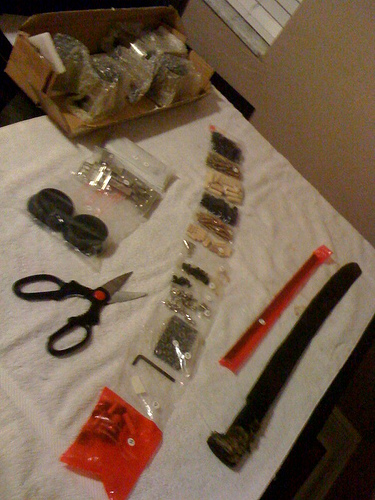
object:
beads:
[160, 336, 166, 345]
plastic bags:
[108, 351, 183, 428]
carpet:
[297, 406, 362, 498]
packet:
[60, 387, 162, 499]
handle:
[207, 404, 258, 468]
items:
[11, 270, 146, 359]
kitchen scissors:
[13, 269, 149, 356]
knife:
[206, 262, 362, 467]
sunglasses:
[28, 186, 109, 257]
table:
[0, 85, 375, 498]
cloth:
[0, 83, 375, 498]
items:
[48, 29, 97, 106]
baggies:
[82, 56, 119, 121]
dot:
[93, 285, 105, 302]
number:
[127, 435, 135, 447]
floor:
[181, 0, 375, 247]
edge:
[105, 385, 160, 435]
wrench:
[130, 354, 175, 385]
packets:
[218, 245, 333, 370]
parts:
[170, 172, 225, 322]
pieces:
[200, 214, 213, 225]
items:
[152, 55, 184, 106]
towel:
[1, 84, 375, 499]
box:
[4, 6, 213, 141]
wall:
[182, 0, 375, 248]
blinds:
[204, 2, 304, 60]